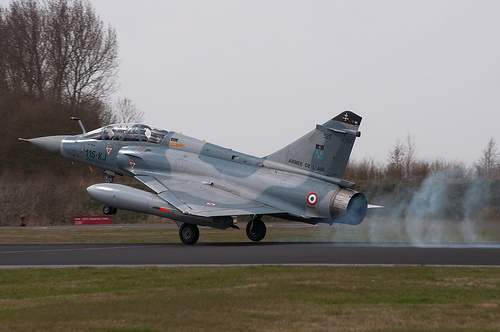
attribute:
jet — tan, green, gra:
[17, 109, 368, 239]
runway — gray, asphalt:
[142, 246, 188, 261]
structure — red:
[67, 210, 114, 227]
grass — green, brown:
[80, 275, 126, 298]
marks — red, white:
[301, 188, 318, 208]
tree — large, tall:
[3, 11, 109, 116]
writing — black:
[290, 158, 334, 179]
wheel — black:
[175, 224, 201, 246]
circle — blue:
[306, 188, 323, 202]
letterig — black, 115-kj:
[87, 146, 106, 160]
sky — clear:
[201, 26, 258, 81]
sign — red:
[71, 209, 112, 223]